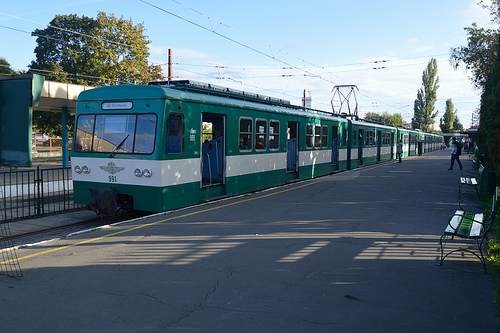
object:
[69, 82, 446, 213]
train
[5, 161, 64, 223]
gate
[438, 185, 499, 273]
benches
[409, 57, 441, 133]
trees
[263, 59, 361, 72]
telephone wires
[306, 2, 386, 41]
sky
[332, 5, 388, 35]
blue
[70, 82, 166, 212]
front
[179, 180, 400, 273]
platform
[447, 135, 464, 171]
person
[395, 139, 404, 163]
person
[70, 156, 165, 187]
white strip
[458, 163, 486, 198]
bench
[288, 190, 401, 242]
side walk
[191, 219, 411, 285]
shadows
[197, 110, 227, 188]
train door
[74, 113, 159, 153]
windshield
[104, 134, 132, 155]
wipers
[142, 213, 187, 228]
stripe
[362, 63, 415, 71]
cables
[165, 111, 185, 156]
window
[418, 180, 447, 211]
concrete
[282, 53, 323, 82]
wires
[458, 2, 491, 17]
clouds